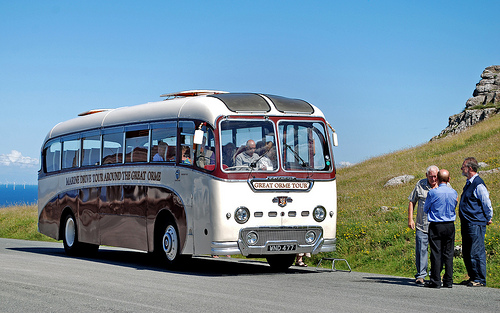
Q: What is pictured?
A: A bus.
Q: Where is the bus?
A: Tennessee.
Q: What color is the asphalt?
A: Black.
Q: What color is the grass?
A: Green.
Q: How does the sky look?
A: Partly cloudy.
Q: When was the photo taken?
A: Last week.